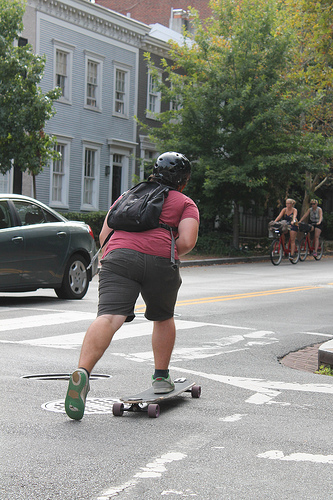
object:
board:
[110, 348, 201, 427]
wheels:
[148, 404, 163, 419]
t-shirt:
[101, 185, 199, 259]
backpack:
[107, 184, 161, 230]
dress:
[283, 213, 295, 226]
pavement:
[0, 296, 330, 495]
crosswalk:
[191, 298, 323, 388]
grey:
[157, 278, 173, 292]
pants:
[98, 247, 180, 324]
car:
[1, 191, 87, 301]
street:
[3, 253, 327, 498]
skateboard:
[119, 357, 232, 430]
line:
[22, 316, 206, 348]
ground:
[205, 349, 330, 497]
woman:
[276, 200, 297, 258]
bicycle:
[269, 228, 299, 263]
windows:
[50, 37, 132, 120]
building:
[0, 0, 181, 215]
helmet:
[148, 144, 191, 186]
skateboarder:
[62, 144, 200, 408]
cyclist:
[270, 193, 327, 266]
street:
[205, 269, 316, 317]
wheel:
[187, 386, 204, 400]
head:
[155, 151, 196, 180]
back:
[104, 186, 181, 260]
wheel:
[61, 256, 94, 309]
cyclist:
[300, 196, 324, 260]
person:
[62, 137, 198, 419]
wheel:
[110, 401, 126, 421]